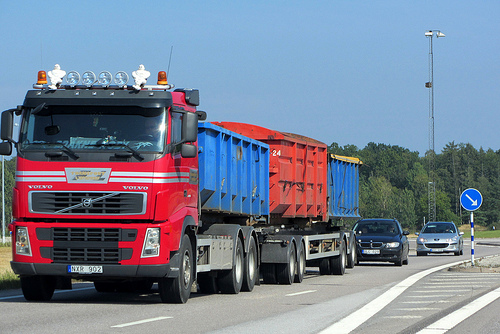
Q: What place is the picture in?
A: It is at the road.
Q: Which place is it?
A: It is a road.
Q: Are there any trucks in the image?
A: Yes, there is a truck.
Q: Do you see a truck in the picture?
A: Yes, there is a truck.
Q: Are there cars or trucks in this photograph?
A: Yes, there is a truck.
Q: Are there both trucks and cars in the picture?
A: Yes, there are both a truck and a car.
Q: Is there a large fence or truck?
A: Yes, there is a large truck.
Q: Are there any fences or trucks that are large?
A: Yes, the truck is large.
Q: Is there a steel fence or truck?
A: Yes, there is a steel truck.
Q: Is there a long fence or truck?
A: Yes, there is a long truck.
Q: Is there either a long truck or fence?
A: Yes, there is a long truck.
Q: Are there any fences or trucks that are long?
A: Yes, the truck is long.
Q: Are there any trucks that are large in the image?
A: Yes, there is a large truck.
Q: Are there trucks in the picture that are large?
A: Yes, there is a truck that is large.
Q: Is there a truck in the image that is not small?
A: Yes, there is a large truck.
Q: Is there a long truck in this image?
A: Yes, there is a long truck.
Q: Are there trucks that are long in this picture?
A: Yes, there is a long truck.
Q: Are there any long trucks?
A: Yes, there is a long truck.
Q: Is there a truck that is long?
A: Yes, there is a truck that is long.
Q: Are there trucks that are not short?
A: Yes, there is a long truck.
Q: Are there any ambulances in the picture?
A: No, there are no ambulances.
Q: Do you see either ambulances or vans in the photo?
A: No, there are no ambulances or vans.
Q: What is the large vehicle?
A: The vehicle is a truck.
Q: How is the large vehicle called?
A: The vehicle is a truck.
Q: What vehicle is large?
A: The vehicle is a truck.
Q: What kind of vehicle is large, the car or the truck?
A: The truck is large.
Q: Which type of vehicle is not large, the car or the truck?
A: The car is not large.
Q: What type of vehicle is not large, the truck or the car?
A: The car is not large.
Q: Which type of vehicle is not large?
A: The vehicle is a car.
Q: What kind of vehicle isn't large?
A: The vehicle is a car.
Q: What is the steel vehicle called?
A: The vehicle is a truck.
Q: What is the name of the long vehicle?
A: The vehicle is a truck.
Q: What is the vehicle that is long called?
A: The vehicle is a truck.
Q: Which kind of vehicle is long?
A: The vehicle is a truck.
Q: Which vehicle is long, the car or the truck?
A: The truck is long.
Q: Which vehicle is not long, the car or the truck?
A: The car is not long.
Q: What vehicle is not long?
A: The vehicle is a car.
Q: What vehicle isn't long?
A: The vehicle is a car.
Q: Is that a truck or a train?
A: That is a truck.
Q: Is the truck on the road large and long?
A: Yes, the truck is large and long.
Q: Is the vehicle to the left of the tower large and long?
A: Yes, the truck is large and long.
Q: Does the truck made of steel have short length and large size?
A: No, the truck is large but long.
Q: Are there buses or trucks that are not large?
A: No, there is a truck but it is large.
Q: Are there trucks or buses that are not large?
A: No, there is a truck but it is large.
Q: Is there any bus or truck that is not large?
A: No, there is a truck but it is large.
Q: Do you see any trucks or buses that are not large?
A: No, there is a truck but it is large.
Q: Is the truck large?
A: Yes, the truck is large.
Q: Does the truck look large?
A: Yes, the truck is large.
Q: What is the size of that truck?
A: The truck is large.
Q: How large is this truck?
A: The truck is large.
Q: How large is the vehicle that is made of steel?
A: The truck is large.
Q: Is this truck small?
A: No, the truck is large.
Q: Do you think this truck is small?
A: No, the truck is large.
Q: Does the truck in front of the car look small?
A: No, the truck is large.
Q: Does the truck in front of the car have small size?
A: No, the truck is large.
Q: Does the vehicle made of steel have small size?
A: No, the truck is large.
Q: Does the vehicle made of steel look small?
A: No, the truck is large.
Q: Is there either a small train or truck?
A: No, there is a truck but it is large.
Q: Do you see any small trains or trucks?
A: No, there is a truck but it is large.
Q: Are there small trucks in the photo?
A: No, there is a truck but it is large.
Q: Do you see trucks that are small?
A: No, there is a truck but it is large.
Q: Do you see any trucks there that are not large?
A: No, there is a truck but it is large.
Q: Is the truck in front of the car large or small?
A: The truck is large.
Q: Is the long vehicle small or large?
A: The truck is large.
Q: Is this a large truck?
A: Yes, this is a large truck.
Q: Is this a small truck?
A: No, this is a large truck.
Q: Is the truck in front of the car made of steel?
A: Yes, the truck is made of steel.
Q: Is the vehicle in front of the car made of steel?
A: Yes, the truck is made of steel.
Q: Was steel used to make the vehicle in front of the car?
A: Yes, the truck is made of steel.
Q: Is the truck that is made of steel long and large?
A: Yes, the truck is long and large.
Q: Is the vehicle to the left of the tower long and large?
A: Yes, the truck is long and large.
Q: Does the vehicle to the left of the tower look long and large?
A: Yes, the truck is long and large.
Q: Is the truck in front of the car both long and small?
A: No, the truck is long but large.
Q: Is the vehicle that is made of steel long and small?
A: No, the truck is long but large.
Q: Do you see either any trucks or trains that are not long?
A: No, there is a truck but it is long.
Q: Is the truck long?
A: Yes, the truck is long.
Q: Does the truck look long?
A: Yes, the truck is long.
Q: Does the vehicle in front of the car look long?
A: Yes, the truck is long.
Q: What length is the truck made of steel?
A: The truck is long.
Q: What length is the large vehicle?
A: The truck is long.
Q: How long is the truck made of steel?
A: The truck is long.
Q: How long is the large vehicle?
A: The truck is long.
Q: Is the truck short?
A: No, the truck is long.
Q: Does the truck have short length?
A: No, the truck is long.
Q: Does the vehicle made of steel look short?
A: No, the truck is long.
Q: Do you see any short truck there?
A: No, there is a truck but it is long.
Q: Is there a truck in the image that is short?
A: No, there is a truck but it is long.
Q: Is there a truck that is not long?
A: No, there is a truck but it is long.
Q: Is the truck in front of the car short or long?
A: The truck is long.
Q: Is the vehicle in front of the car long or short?
A: The truck is long.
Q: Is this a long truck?
A: Yes, this is a long truck.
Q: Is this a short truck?
A: No, this is a long truck.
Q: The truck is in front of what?
A: The truck is in front of the car.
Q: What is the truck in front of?
A: The truck is in front of the car.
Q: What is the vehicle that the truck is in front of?
A: The vehicle is a car.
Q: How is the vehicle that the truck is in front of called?
A: The vehicle is a car.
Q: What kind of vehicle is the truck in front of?
A: The truck is in front of the car.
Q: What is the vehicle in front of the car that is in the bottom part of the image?
A: The vehicle is a truck.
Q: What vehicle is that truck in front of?
A: The truck is in front of the car.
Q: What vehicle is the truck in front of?
A: The truck is in front of the car.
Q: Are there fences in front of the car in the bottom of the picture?
A: No, there is a truck in front of the car.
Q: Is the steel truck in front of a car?
A: Yes, the truck is in front of a car.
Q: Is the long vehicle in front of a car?
A: Yes, the truck is in front of a car.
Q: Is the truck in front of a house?
A: No, the truck is in front of a car.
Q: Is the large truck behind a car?
A: No, the truck is in front of a car.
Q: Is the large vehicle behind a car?
A: No, the truck is in front of a car.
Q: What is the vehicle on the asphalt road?
A: The vehicle is a truck.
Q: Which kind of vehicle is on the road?
A: The vehicle is a truck.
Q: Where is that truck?
A: The truck is on the road.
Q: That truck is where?
A: The truck is on the road.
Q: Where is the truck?
A: The truck is on the road.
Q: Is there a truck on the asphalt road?
A: Yes, there is a truck on the road.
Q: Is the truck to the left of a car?
A: Yes, the truck is to the left of a car.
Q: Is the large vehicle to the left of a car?
A: Yes, the truck is to the left of a car.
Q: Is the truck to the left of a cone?
A: No, the truck is to the left of a car.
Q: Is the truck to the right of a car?
A: No, the truck is to the left of a car.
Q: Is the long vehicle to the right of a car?
A: No, the truck is to the left of a car.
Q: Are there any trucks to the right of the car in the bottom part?
A: No, the truck is to the left of the car.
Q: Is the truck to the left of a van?
A: No, the truck is to the left of the car.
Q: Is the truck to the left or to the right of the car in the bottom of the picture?
A: The truck is to the left of the car.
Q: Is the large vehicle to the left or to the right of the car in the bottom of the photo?
A: The truck is to the left of the car.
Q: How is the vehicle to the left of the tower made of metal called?
A: The vehicle is a truck.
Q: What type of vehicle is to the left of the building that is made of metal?
A: The vehicle is a truck.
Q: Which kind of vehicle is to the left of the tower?
A: The vehicle is a truck.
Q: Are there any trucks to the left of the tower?
A: Yes, there is a truck to the left of the tower.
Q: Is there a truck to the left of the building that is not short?
A: Yes, there is a truck to the left of the tower.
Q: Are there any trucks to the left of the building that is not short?
A: Yes, there is a truck to the left of the tower.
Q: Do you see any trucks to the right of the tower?
A: No, the truck is to the left of the tower.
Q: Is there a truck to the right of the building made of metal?
A: No, the truck is to the left of the tower.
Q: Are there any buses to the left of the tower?
A: No, there is a truck to the left of the tower.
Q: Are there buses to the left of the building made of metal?
A: No, there is a truck to the left of the tower.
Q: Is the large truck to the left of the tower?
A: Yes, the truck is to the left of the tower.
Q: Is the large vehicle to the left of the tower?
A: Yes, the truck is to the left of the tower.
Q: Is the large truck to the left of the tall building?
A: Yes, the truck is to the left of the tower.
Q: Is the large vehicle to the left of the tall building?
A: Yes, the truck is to the left of the tower.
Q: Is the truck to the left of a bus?
A: No, the truck is to the left of the tower.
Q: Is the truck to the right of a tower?
A: No, the truck is to the left of a tower.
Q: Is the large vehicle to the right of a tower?
A: No, the truck is to the left of a tower.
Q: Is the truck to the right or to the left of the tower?
A: The truck is to the left of the tower.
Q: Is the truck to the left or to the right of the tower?
A: The truck is to the left of the tower.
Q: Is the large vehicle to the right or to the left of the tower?
A: The truck is to the left of the tower.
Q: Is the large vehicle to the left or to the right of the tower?
A: The truck is to the left of the tower.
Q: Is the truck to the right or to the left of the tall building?
A: The truck is to the left of the tower.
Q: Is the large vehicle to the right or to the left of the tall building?
A: The truck is to the left of the tower.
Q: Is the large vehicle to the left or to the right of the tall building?
A: The truck is to the left of the tower.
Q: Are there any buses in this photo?
A: No, there are no buses.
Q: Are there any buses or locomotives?
A: No, there are no buses or locomotives.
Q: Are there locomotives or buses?
A: No, there are no buses or locomotives.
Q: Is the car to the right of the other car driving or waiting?
A: The car is driving.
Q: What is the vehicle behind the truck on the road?
A: The vehicle is a car.